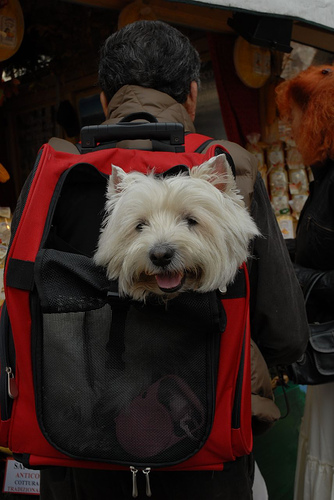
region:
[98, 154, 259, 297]
Head of a white dog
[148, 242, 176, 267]
Nose of a white dog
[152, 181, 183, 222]
White fur of a dog's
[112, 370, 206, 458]
Leash behind a bag's mesh pocket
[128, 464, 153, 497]
Handles for a zipper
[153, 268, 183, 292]
Pink tongue on a dog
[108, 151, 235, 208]
Ears on a dog's head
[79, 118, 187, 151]
A black handle of a bag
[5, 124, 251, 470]
A red backpack with a dog inside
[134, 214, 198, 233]
A dog's black eyes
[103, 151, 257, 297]
white long haired dog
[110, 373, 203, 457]
pink leash in the bag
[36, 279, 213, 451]
black netting on the bag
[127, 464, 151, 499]
two silver zipper pulls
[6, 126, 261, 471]
red and black backpack the man is wearing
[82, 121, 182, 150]
black handle on the bag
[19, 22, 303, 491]
man wearing the backpack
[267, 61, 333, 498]
woman with red hair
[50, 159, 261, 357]
dog riding in a backpack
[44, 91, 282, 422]
brown vest the man is wearing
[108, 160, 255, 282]
the dog is white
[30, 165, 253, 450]
the dog is in the bag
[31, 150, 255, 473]
the bag is red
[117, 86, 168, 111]
the jacket is brown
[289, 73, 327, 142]
the hair is brown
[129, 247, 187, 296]
the mouth is open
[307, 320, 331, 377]
the bag is blackin color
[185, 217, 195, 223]
the eyes are black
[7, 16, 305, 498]
the man is carrying a bag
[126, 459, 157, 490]
two zippers are on the bag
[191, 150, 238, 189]
ear of a white dog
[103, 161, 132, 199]
ear of a white dog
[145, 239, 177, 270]
nose of a white dog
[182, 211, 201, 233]
eye of a white dog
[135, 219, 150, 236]
eye of a white dog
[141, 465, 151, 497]
metal zipper on a back pack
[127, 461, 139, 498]
metal zipper on a back pack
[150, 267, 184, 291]
tongue of a white dog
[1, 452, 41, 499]
red and white sign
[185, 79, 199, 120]
ear of a person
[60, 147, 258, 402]
a white dog in a back pack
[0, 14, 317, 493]
a man with a pack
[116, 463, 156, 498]
two silver zipper on pack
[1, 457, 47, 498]
a red and white sign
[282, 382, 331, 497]
a lace white skirt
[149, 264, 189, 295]
a pink tougne of dog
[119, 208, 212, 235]
mostly hair covered eyes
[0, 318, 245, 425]
part of red and black backpack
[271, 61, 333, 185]
a red fussy hair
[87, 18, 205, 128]
the back of a man's head